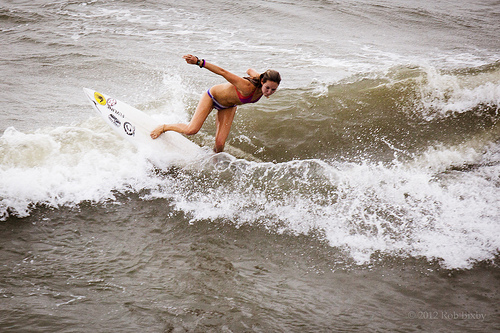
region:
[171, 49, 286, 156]
woman surfing in the ocean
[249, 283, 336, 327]
dirty ocean water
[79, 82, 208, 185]
white surfboard in ocean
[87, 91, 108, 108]
yellow logo on a surfboard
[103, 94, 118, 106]
red and blue logo on surfboard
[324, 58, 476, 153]
wave in the ocean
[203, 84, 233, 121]
blue and white bikini bottom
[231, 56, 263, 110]
a red bikini top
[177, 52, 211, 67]
colorful bands on arms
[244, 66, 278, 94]
brown hair on woman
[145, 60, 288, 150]
a surfer in a bikini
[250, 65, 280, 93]
wet hair on a surfer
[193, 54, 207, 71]
a wristband on a surfer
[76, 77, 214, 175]
a white and yellow surfboard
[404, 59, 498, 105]
the top of a wave rolling over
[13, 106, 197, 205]
white water by a surf board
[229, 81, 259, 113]
a red bikini top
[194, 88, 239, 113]
a blue and white striped bikini bottom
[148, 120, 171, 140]
a bare foot on a surfboard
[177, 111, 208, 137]
a bent knee on a surfer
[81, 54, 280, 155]
woman surfing ocean waves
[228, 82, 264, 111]
woman's red bikini top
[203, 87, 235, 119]
purple and white bikini bottom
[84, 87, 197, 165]
surfboard riding the waves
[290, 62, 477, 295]
oceans breaking and foaming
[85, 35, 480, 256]
woman surfing small waves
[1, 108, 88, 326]
small ocean wave foaming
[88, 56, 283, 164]
woman surfing and leaning forward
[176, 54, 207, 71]
multicolored wristbands on right wrist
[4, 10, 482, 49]
calm ocean without waves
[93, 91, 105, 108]
Yellow and black logo on surfboard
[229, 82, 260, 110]
Tiny red top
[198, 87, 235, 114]
Multi-colored bikini bottoms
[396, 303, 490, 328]
Photographer watermark on lower right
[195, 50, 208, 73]
Jewelry on surfer's wrist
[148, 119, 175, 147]
Back foot of surfer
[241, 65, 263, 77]
Back arm of surfer visible behind head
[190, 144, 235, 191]
Splash hiding foot of surfer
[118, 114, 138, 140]
Black circular logo on surfboard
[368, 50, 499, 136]
Cresting wave on right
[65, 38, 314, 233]
woman with one foot on surf board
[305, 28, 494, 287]
churning waves in the ocean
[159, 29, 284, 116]
woman with red bikini top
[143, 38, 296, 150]
woman with purple bikini bottom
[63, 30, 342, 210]
woman getting ready to dive from surfboard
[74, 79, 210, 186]
white surfboard in waves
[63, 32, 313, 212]
woman on white surf board in waves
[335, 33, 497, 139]
an ocean wave curling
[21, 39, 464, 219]
woman and surf board in waves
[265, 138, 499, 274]
white froth on ocean wave